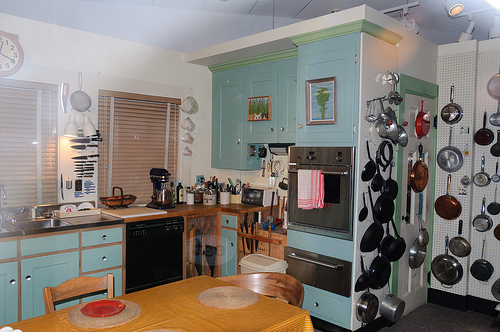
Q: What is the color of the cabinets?
A: Light blue.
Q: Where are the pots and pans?
A: Hanging on the wall.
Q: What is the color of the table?
A: Tan.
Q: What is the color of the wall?
A: White.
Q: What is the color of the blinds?
A: Light brown.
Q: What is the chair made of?
A: Wood.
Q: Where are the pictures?
A: On the cabinets.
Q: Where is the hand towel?
A: On the oven handle.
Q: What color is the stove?
A: Silver.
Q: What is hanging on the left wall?
A: Black pans.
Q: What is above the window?
A: A clock.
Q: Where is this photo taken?
A: A kitchen.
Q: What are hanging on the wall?
A: Frying pans.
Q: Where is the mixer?
A: On the counter.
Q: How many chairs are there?
A: Two.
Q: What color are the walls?
A: Blue and white.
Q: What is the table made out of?
A: Wood.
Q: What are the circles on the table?
A: Placemats.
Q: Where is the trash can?
A: By the oven.